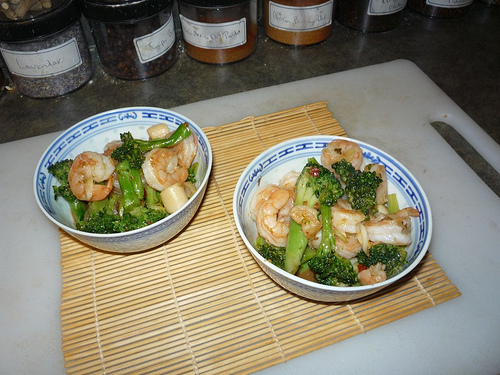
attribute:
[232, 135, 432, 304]
bowl — white, blue, ceramic bowls, plastic bowl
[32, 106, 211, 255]
bowl — identical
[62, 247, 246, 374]
place mat — small, bamboo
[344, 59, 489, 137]
cutting board — white plastic, white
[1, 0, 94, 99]
containers — clear glass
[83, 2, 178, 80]
spices — labeled, clear glass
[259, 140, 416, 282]
food — shrimp, broccoli, cooked shrimp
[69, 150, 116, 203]
shrimp — big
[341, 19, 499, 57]
counter top — granite, dark marble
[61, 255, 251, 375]
mat — place mat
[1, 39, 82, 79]
label — white